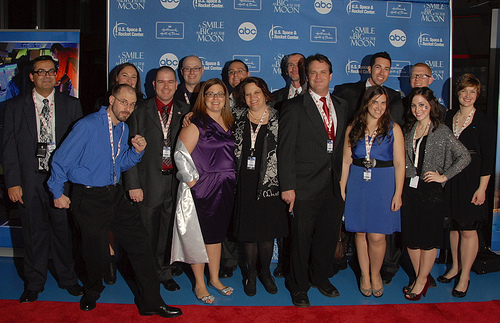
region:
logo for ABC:
[388, 29, 406, 44]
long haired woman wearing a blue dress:
[341, 84, 401, 299]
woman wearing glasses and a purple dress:
[181, 80, 238, 297]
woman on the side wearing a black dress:
[448, 75, 488, 300]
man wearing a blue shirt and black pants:
[48, 83, 177, 319]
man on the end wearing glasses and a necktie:
[2, 56, 89, 299]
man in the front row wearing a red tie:
[282, 53, 339, 304]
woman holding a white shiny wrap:
[171, 78, 231, 306]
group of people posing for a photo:
[3, 55, 487, 301]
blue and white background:
[118, 5, 442, 48]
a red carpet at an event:
[0, 298, 499, 322]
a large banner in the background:
[0, 28, 80, 248]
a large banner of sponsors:
[106, 0, 451, 99]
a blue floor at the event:
[0, 254, 499, 306]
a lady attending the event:
[338, 85, 405, 298]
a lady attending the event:
[399, 85, 471, 300]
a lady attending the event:
[436, 73, 491, 298]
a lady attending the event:
[170, 78, 236, 304]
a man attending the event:
[46, 83, 182, 316]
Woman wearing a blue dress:
[334, 94, 409, 299]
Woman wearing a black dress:
[438, 76, 499, 300]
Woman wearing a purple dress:
[170, 76, 244, 308]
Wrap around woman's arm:
[166, 143, 216, 271]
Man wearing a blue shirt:
[44, 82, 183, 319]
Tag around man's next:
[96, 108, 128, 192]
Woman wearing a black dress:
[224, 82, 291, 300]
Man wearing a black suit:
[2, 58, 94, 305]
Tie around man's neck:
[34, 95, 55, 165]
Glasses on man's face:
[28, 65, 56, 80]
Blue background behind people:
[107, 0, 457, 226]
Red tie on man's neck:
[311, 91, 336, 146]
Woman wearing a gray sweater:
[398, 85, 467, 303]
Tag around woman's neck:
[410, 122, 436, 189]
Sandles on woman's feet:
[193, 276, 240, 308]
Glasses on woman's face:
[198, 85, 226, 102]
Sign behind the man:
[3, 23, 87, 260]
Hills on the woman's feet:
[402, 268, 430, 308]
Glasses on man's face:
[224, 65, 246, 79]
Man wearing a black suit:
[333, 33, 406, 131]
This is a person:
[438, 68, 487, 301]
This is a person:
[401, 88, 455, 313]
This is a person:
[337, 85, 407, 303]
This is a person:
[293, 50, 350, 314]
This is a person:
[233, 69, 288, 311]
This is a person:
[175, 75, 242, 312]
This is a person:
[134, 62, 199, 318]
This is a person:
[52, 90, 157, 318]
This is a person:
[13, 47, 93, 312]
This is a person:
[173, 50, 204, 212]